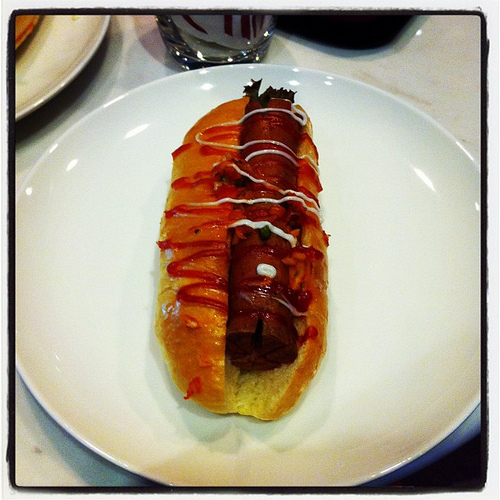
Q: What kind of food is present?
A: Hot dog.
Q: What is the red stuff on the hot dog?
A: Ketchup.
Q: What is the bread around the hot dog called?
A: Bun.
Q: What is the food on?
A: Plate.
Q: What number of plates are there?
A: 2.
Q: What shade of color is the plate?
A: White.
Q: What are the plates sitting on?
A: Table.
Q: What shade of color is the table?
A: White.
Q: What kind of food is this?
A: Hot dog.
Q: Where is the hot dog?
A: White plate.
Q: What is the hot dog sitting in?
A: Bun.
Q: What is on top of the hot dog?
A: Ketchup.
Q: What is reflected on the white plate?
A: White light.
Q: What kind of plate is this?
A: Round and white.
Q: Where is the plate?
A: White table.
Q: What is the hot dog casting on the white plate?
A: Shadow.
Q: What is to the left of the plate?
A: Another plate.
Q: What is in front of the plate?
A: Dark object.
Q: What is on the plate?
A: Hot Dog.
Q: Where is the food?
A: On the plate.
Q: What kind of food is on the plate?
A: Hot Dog.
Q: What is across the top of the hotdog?
A: Condiments.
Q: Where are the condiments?
A: On the hotdog.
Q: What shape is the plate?
A: Round.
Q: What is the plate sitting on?
A: A table.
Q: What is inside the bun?
A: A sausage.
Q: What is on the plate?
A: A sausage on a bun.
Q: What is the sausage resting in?
A: A bun.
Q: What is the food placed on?
A: A white plate.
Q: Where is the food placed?
A: On a plate.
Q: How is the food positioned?
A: Vertically.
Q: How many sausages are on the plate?
A: One.